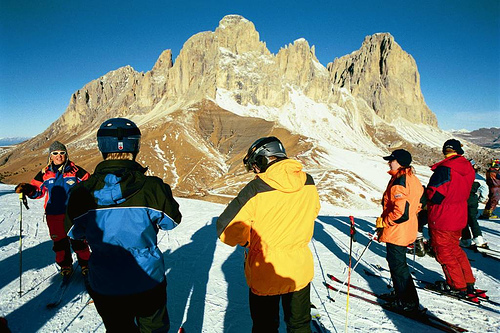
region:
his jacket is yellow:
[255, 194, 307, 278]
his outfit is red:
[435, 160, 481, 262]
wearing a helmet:
[240, 129, 285, 176]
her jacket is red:
[47, 156, 84, 255]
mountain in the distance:
[30, 30, 431, 194]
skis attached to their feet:
[289, 275, 434, 322]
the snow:
[338, 307, 366, 330]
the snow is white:
[181, 202, 208, 222]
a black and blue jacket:
[79, 190, 164, 287]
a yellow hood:
[268, 166, 309, 188]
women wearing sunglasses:
[52, 150, 67, 158]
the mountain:
[196, 32, 253, 79]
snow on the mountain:
[235, 84, 264, 120]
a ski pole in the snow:
[343, 257, 356, 320]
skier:
[67, 108, 178, 325]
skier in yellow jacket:
[231, 148, 319, 312]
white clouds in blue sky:
[435, 33, 476, 70]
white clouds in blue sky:
[71, 19, 141, 39]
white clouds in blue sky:
[32, 25, 77, 70]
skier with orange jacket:
[368, 155, 438, 329]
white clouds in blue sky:
[428, 23, 466, 61]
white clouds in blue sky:
[430, 65, 467, 110]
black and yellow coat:
[231, 173, 326, 288]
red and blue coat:
[35, 159, 80, 234]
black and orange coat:
[350, 162, 431, 267]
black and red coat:
[425, 142, 495, 258]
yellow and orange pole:
[316, 221, 371, 328]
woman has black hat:
[385, 135, 422, 173]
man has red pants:
[425, 214, 495, 296]